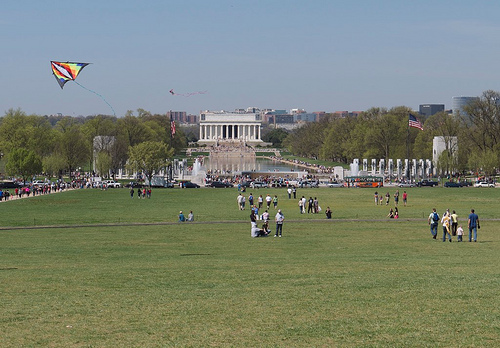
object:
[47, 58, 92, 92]
kite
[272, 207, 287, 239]
people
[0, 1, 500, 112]
sky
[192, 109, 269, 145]
building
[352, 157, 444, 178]
feature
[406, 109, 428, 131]
flag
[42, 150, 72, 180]
trees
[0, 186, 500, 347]
lawn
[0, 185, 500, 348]
mall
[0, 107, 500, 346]
park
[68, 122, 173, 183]
side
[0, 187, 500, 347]
grass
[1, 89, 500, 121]
skyline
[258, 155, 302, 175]
pool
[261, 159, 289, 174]
water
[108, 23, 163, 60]
air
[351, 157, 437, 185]
fountain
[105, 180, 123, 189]
bus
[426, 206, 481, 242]
crowd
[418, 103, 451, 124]
high rises